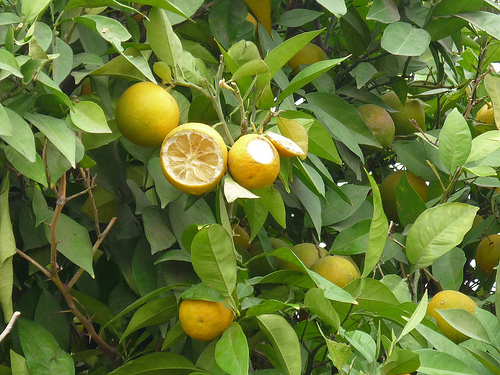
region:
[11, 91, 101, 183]
bright green leaves on a tree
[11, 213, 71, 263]
a brown skinny twig branch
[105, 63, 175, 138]
a lemon that is not rip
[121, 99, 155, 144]
the green color of a ripe lemon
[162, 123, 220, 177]
a lemon that was cut open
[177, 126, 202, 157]
the pulp of a lemon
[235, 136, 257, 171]
the peel of a fruit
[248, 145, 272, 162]
the white inside of a peel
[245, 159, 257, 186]
a stain on a fruit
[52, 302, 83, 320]
the thorns on a twig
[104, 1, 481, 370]
lemons on trees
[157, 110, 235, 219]
a lemon that looks like it was cut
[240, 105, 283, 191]
the white rind of the lemon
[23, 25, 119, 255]
the green leaves from the lemon trees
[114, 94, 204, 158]
a yellow and green lemon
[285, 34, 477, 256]
unrippened lemons on the tree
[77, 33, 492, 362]
many lemons waiting to be picked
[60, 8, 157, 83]
leaves that have bug bites on them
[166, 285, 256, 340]
a lemon ready to be picked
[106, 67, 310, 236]
lemons on a tree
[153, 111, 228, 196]
there is a chunk missing from this lemon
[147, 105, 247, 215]
this lemon has been sliced open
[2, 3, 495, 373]
this is a lemon tree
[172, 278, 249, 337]
a yellow lemon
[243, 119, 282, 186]
this part is white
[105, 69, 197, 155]
this lemon is yellow and green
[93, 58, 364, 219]
lemons still on a branch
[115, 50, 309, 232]
the lemons are still on the stem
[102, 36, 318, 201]
lemons still on a tree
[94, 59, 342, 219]
a bunch of citrus fruit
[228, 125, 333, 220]
partially eaten citrus fruit still on the plant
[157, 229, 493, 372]
lemons in their tree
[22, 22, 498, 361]
lemons still on the tree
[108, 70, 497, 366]
a lemon tree with fruit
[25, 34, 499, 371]
lemon tree with fruit in bloom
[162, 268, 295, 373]
a lemon still on the tree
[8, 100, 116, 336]
leaves and branch of a lemon tree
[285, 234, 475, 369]
three lemons still in the tree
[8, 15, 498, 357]
a lemon tree blooming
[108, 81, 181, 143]
Small fruit in a tree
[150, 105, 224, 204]
Small fruit in a tree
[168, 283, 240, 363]
Small fruit in a tree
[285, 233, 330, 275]
Small fruit in a tree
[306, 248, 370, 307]
Small fruit in a tree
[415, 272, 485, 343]
Small fruit in a tree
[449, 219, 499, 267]
Small fruit in a tree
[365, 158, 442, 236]
Small fruit in a tree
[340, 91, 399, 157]
Small fruit in a tree